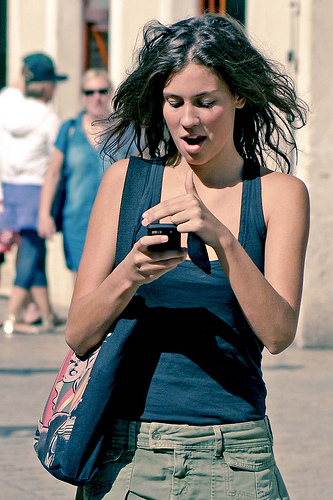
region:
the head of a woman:
[150, 10, 255, 168]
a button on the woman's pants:
[149, 430, 163, 443]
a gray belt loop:
[208, 423, 225, 460]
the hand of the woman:
[139, 167, 232, 251]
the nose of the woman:
[176, 92, 202, 131]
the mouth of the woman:
[176, 128, 214, 156]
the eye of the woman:
[193, 92, 222, 112]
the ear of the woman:
[232, 91, 250, 110]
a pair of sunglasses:
[79, 83, 112, 97]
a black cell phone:
[143, 221, 184, 256]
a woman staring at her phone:
[81, 18, 320, 310]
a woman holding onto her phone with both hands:
[87, 142, 324, 399]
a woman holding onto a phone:
[81, 174, 269, 399]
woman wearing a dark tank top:
[85, 139, 329, 394]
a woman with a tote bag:
[31, 222, 194, 498]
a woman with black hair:
[80, 13, 326, 240]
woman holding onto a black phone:
[130, 186, 279, 352]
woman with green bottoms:
[29, 380, 300, 493]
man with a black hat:
[21, 51, 157, 274]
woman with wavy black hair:
[102, 18, 331, 203]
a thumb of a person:
[182, 168, 203, 192]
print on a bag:
[52, 360, 95, 386]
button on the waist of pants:
[144, 424, 169, 446]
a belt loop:
[203, 422, 226, 461]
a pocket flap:
[224, 447, 276, 473]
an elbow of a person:
[253, 317, 294, 359]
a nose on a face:
[178, 110, 201, 131]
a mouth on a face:
[178, 130, 210, 151]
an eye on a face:
[193, 93, 219, 112]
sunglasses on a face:
[81, 86, 117, 96]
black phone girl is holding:
[143, 209, 192, 277]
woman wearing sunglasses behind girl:
[78, 66, 114, 115]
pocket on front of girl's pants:
[219, 447, 280, 498]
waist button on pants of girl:
[147, 422, 170, 451]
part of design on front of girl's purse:
[60, 357, 94, 461]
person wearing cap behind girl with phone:
[19, 58, 69, 107]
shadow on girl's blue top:
[164, 298, 236, 385]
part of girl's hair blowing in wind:
[268, 88, 309, 173]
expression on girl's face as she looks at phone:
[160, 83, 225, 161]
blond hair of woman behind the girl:
[76, 67, 112, 100]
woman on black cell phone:
[89, 192, 290, 336]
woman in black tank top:
[62, 144, 282, 449]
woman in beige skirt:
[31, 401, 299, 495]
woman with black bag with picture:
[31, 297, 184, 438]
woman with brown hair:
[104, 18, 305, 175]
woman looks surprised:
[123, 30, 239, 178]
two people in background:
[16, 26, 116, 239]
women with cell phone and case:
[159, 182, 213, 285]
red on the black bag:
[28, 294, 141, 498]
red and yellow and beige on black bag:
[47, 321, 101, 473]